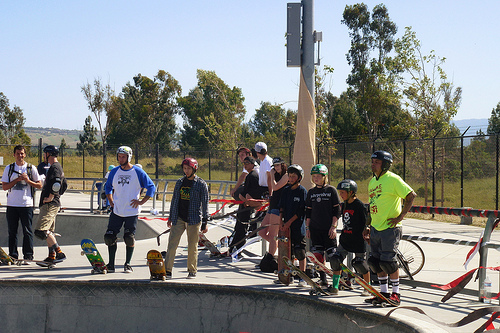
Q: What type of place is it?
A: It is a park.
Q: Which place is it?
A: It is a park.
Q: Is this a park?
A: Yes, it is a park.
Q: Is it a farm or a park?
A: It is a park.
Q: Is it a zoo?
A: No, it is a park.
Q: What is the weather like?
A: It is sunny.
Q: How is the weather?
A: It is sunny.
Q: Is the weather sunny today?
A: Yes, it is sunny.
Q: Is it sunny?
A: Yes, it is sunny.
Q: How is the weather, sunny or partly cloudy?
A: It is sunny.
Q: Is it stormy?
A: No, it is sunny.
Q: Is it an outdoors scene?
A: Yes, it is outdoors.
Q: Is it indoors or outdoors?
A: It is outdoors.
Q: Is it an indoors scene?
A: No, it is outdoors.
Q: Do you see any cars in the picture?
A: No, there are no cars.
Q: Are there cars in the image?
A: No, there are no cars.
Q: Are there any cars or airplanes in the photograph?
A: No, there are no cars or airplanes.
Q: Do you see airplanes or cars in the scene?
A: No, there are no cars or airplanes.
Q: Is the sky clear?
A: Yes, the sky is clear.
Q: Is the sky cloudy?
A: No, the sky is clear.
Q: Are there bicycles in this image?
A: Yes, there is a bicycle.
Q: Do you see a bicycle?
A: Yes, there is a bicycle.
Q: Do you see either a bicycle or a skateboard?
A: Yes, there is a bicycle.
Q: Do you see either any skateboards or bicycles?
A: Yes, there is a bicycle.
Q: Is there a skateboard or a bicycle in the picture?
A: Yes, there is a bicycle.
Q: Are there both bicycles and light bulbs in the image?
A: No, there is a bicycle but no light bulbs.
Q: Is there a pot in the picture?
A: No, there are no pots.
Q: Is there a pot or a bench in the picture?
A: No, there are no pots or benches.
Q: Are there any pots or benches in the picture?
A: No, there are no pots or benches.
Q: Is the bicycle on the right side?
A: Yes, the bicycle is on the right of the image.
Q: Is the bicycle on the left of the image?
A: No, the bicycle is on the right of the image.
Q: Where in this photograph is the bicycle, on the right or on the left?
A: The bicycle is on the right of the image.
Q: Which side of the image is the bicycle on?
A: The bicycle is on the right of the image.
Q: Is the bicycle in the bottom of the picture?
A: Yes, the bicycle is in the bottom of the image.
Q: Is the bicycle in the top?
A: No, the bicycle is in the bottom of the image.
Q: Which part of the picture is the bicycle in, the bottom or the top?
A: The bicycle is in the bottom of the image.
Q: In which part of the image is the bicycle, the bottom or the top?
A: The bicycle is in the bottom of the image.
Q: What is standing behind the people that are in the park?
A: The bicycle is standing behind the people.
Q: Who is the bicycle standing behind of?
A: The bicycle is standing behind the people.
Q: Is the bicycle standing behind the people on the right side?
A: Yes, the bicycle is standing behind the people.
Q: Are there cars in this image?
A: No, there are no cars.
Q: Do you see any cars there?
A: No, there are no cars.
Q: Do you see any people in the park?
A: Yes, there are people in the park.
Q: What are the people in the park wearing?
A: The people are wearing a helmet.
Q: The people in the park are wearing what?
A: The people are wearing a helmet.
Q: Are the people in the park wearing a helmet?
A: Yes, the people are wearing a helmet.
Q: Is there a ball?
A: No, there are no balls.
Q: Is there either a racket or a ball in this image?
A: No, there are no balls or rackets.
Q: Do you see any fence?
A: Yes, there is a fence.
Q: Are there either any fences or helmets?
A: Yes, there is a fence.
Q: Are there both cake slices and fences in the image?
A: No, there is a fence but no cake slices.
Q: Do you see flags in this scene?
A: No, there are no flags.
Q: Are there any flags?
A: No, there are no flags.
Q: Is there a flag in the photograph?
A: No, there are no flags.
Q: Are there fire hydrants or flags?
A: No, there are no flags or fire hydrants.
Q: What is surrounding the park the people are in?
A: The fence is surrounding the park.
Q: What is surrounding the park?
A: The fence is surrounding the park.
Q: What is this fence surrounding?
A: The fence is surrounding the park.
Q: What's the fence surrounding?
A: The fence is surrounding the park.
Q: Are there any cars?
A: No, there are no cars.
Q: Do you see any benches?
A: No, there are no benches.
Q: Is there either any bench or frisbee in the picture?
A: No, there are no benches or frisbees.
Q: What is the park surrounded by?
A: The park is surrounded by the fence.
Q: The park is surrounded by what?
A: The park is surrounded by the fence.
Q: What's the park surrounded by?
A: The park is surrounded by the fence.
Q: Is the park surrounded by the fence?
A: Yes, the park is surrounded by the fence.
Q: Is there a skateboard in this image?
A: Yes, there is a skateboard.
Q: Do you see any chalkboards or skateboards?
A: Yes, there is a skateboard.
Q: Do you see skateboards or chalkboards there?
A: Yes, there is a skateboard.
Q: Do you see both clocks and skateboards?
A: No, there is a skateboard but no clocks.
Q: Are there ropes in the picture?
A: No, there are no ropes.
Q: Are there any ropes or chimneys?
A: No, there are no ropes or chimneys.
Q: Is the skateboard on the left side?
A: Yes, the skateboard is on the left of the image.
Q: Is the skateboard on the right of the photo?
A: No, the skateboard is on the left of the image.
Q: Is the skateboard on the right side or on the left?
A: The skateboard is on the left of the image.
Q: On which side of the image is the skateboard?
A: The skateboard is on the left of the image.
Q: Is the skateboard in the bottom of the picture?
A: Yes, the skateboard is in the bottom of the image.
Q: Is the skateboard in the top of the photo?
A: No, the skateboard is in the bottom of the image.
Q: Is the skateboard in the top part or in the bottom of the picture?
A: The skateboard is in the bottom of the image.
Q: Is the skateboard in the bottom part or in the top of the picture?
A: The skateboard is in the bottom of the image.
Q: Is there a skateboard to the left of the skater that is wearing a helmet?
A: Yes, there is a skateboard to the left of the skater.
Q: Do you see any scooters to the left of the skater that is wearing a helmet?
A: No, there is a skateboard to the left of the skater.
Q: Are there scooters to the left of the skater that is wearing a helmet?
A: No, there is a skateboard to the left of the skater.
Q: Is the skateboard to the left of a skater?
A: Yes, the skateboard is to the left of a skater.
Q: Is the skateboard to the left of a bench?
A: No, the skateboard is to the left of a skater.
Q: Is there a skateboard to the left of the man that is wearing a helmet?
A: Yes, there is a skateboard to the left of the man.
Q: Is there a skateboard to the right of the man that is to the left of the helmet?
A: No, the skateboard is to the left of the man.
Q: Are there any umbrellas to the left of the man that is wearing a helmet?
A: No, there is a skateboard to the left of the man.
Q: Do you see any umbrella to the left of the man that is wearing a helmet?
A: No, there is a skateboard to the left of the man.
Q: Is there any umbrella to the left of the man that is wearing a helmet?
A: No, there is a skateboard to the left of the man.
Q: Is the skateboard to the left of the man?
A: Yes, the skateboard is to the left of the man.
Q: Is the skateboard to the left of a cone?
A: No, the skateboard is to the left of the man.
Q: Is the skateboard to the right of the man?
A: No, the skateboard is to the left of the man.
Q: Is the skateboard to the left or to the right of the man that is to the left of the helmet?
A: The skateboard is to the left of the man.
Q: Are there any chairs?
A: No, there are no chairs.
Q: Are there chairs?
A: No, there are no chairs.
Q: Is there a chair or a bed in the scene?
A: No, there are no chairs or beds.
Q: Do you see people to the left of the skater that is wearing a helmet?
A: Yes, there is a person to the left of the skater.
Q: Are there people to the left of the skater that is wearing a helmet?
A: Yes, there is a person to the left of the skater.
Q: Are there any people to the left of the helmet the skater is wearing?
A: Yes, there is a person to the left of the helmet.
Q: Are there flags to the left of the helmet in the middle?
A: No, there is a person to the left of the helmet.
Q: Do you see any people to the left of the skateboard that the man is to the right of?
A: Yes, there is a person to the left of the skateboard.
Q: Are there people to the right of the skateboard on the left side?
A: No, the person is to the left of the skateboard.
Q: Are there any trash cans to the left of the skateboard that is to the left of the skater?
A: No, there is a person to the left of the skateboard.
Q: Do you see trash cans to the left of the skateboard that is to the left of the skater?
A: No, there is a person to the left of the skateboard.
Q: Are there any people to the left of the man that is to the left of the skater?
A: Yes, there is a person to the left of the man.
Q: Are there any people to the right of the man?
A: No, the person is to the left of the man.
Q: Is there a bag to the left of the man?
A: No, there is a person to the left of the man.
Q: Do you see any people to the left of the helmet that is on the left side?
A: Yes, there is a person to the left of the helmet.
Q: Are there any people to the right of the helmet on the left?
A: No, the person is to the left of the helmet.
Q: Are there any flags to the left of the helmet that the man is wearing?
A: No, there is a person to the left of the helmet.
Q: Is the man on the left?
A: Yes, the man is on the left of the image.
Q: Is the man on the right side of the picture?
A: No, the man is on the left of the image.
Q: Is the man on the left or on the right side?
A: The man is on the left of the image.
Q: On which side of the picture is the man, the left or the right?
A: The man is on the left of the image.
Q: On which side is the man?
A: The man is on the left of the image.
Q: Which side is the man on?
A: The man is on the left of the image.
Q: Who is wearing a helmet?
A: The man is wearing a helmet.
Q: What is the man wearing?
A: The man is wearing a helmet.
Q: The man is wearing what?
A: The man is wearing a helmet.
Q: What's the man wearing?
A: The man is wearing a helmet.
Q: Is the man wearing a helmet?
A: Yes, the man is wearing a helmet.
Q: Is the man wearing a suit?
A: No, the man is wearing a helmet.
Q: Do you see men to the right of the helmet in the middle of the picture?
A: No, the man is to the left of the helmet.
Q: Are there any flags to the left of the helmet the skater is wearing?
A: No, there is a man to the left of the helmet.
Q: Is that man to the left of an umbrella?
A: No, the man is to the left of the helmet.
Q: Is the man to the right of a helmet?
A: No, the man is to the left of a helmet.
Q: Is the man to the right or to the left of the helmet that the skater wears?
A: The man is to the left of the helmet.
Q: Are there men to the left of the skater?
A: Yes, there is a man to the left of the skater.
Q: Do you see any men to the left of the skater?
A: Yes, there is a man to the left of the skater.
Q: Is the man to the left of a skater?
A: Yes, the man is to the left of a skater.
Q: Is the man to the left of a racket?
A: No, the man is to the left of a skater.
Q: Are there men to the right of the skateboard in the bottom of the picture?
A: Yes, there is a man to the right of the skateboard.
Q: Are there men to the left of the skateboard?
A: No, the man is to the right of the skateboard.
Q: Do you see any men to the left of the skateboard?
A: No, the man is to the right of the skateboard.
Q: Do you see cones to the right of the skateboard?
A: No, there is a man to the right of the skateboard.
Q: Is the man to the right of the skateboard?
A: Yes, the man is to the right of the skateboard.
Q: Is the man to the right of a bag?
A: No, the man is to the right of the skateboard.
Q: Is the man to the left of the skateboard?
A: No, the man is to the right of the skateboard.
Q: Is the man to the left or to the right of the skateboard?
A: The man is to the right of the skateboard.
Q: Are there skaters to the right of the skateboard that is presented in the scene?
A: Yes, there is a skater to the right of the skateboard.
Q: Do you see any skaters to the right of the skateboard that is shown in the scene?
A: Yes, there is a skater to the right of the skateboard.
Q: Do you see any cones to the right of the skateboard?
A: No, there is a skater to the right of the skateboard.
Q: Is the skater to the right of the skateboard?
A: Yes, the skater is to the right of the skateboard.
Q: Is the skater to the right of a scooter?
A: No, the skater is to the right of the skateboard.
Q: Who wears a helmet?
A: The skater wears a helmet.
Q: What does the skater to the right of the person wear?
A: The skater wears a helmet.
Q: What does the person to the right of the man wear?
A: The skater wears a helmet.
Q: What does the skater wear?
A: The skater wears a helmet.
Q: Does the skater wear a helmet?
A: Yes, the skater wears a helmet.